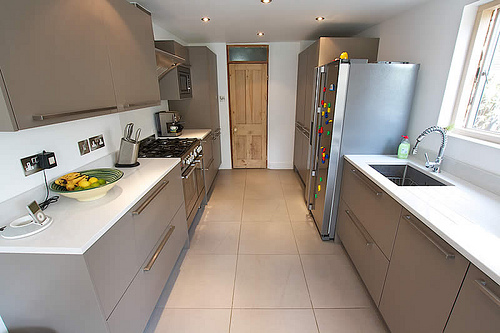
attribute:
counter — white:
[54, 159, 171, 256]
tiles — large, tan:
[178, 167, 367, 305]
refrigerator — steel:
[306, 51, 408, 231]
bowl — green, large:
[43, 166, 128, 202]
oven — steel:
[146, 128, 241, 198]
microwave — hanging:
[154, 46, 219, 117]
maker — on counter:
[144, 98, 208, 148]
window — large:
[435, 15, 499, 162]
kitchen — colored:
[62, 0, 494, 308]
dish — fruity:
[53, 140, 141, 198]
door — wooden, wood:
[217, 47, 271, 193]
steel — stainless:
[279, 30, 372, 163]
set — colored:
[107, 117, 146, 182]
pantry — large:
[189, 45, 235, 184]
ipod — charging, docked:
[31, 187, 49, 226]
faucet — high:
[400, 124, 461, 170]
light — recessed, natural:
[202, 2, 338, 48]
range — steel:
[170, 144, 219, 167]